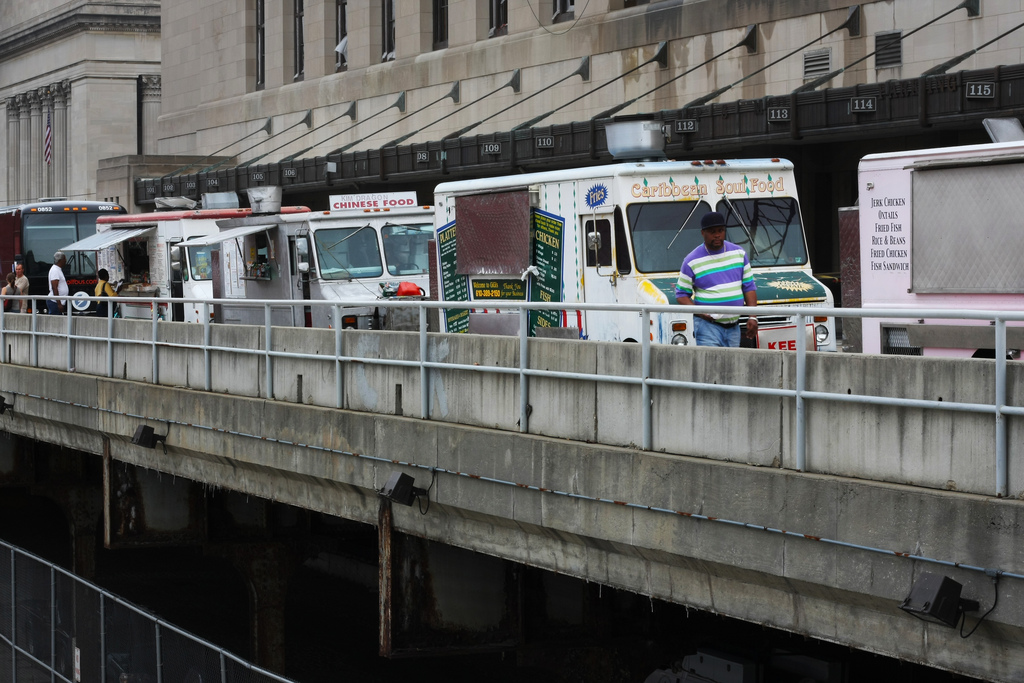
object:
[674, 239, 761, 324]
shirt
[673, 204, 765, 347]
human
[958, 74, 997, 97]
number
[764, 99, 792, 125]
number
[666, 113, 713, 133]
number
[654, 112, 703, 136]
number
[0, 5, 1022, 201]
building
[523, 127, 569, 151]
number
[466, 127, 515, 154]
number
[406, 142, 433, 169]
number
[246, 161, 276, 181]
number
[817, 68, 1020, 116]
wall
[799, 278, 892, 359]
ground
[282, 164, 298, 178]
number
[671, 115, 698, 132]
number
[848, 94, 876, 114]
number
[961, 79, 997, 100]
number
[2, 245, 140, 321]
people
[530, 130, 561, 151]
number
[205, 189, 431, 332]
food truck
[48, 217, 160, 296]
food truck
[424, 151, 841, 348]
food truck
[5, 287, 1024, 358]
street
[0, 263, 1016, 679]
overpass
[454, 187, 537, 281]
window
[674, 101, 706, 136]
number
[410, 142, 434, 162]
number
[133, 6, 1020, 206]
wall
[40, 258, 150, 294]
food